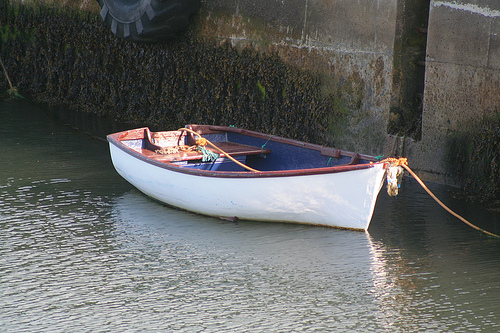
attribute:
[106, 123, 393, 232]
boat — white, wood, tied up, wooden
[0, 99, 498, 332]
water — green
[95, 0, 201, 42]
tire — black, hanging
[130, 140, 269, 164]
seat — brown, empty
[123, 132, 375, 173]
inside — purple, blue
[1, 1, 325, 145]
seaweed — growing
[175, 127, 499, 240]
rope — orange, yellow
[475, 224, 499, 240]
moss — growing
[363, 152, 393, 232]
tip — tied up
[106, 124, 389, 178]
edge — wooden, brownish red